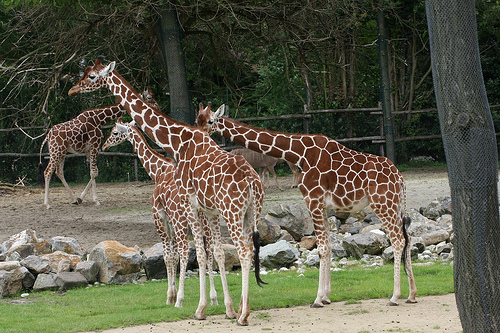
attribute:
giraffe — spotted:
[32, 101, 185, 208]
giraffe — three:
[99, 119, 219, 306]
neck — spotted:
[229, 125, 302, 158]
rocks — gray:
[27, 227, 134, 287]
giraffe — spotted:
[67, 60, 263, 325]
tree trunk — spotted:
[428, 0, 498, 330]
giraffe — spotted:
[37, 57, 330, 331]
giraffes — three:
[52, 41, 465, 321]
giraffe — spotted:
[215, 52, 445, 299]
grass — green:
[0, 260, 455, 331]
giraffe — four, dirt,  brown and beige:
[190, 97, 421, 308]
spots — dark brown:
[186, 162, 232, 238]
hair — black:
[254, 232, 264, 317]